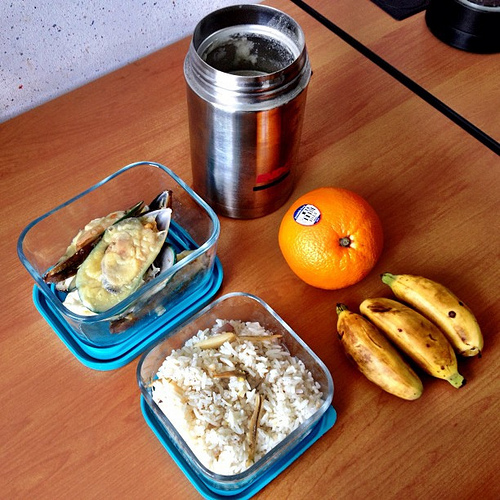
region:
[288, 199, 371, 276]
this is an orange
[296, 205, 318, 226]
this is a sticker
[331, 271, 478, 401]
these are three bananas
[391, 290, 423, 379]
the bananas are yellow in color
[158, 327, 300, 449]
this is a bowl of rice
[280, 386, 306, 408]
the rice is white in color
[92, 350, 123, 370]
this is a lid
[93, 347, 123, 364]
the lid is blue in color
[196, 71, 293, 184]
this is a flask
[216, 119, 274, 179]
the flask is metallic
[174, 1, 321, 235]
stainless steel metal container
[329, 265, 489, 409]
three ripe plantains on table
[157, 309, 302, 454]
white rice in container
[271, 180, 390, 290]
orange with sticker on table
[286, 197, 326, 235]
sticker on orange skin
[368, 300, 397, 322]
dark mark on plantain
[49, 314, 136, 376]
blue plastic cover under container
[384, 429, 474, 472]
wood grain in table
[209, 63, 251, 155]
light reflection on metal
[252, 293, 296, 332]
rim of clear container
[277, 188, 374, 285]
An orange on the table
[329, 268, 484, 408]
three small bananas on the table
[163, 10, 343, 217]
silver drinking flask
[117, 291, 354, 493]
square glass dish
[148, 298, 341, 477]
glass dish with rice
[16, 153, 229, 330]
a rectangular glass dish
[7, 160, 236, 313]
rectangular dish with food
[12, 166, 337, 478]
two open glass dishes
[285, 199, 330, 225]
price sticker on the orange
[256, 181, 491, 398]
fruit on the table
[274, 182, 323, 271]
White and blue sticker on orange.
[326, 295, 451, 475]
Small banana near 2 other bananas.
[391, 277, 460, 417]
3 ripe small bananas sitting on table.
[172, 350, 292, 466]
White rice in small container.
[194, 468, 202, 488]
Container has blue lid under it.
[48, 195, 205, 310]
Oysters in small clear container.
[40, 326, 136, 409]
Blue lid underneath small container.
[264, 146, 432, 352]
Large orange next to bananas.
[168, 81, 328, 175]
Silver container next to orange.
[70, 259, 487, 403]
Food sitting on wood table.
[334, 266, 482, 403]
three small bananas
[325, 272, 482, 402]
brown and yellow bananas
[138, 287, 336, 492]
square glass container filled with rice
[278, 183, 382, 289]
orange with white and blue sticker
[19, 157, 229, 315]
rectangular container with oysters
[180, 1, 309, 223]
thick metal thermos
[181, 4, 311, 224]
metal thermos with red lettering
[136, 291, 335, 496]
glass container with light blue top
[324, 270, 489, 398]
three overripe bananas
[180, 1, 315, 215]
metal thermos containing soup